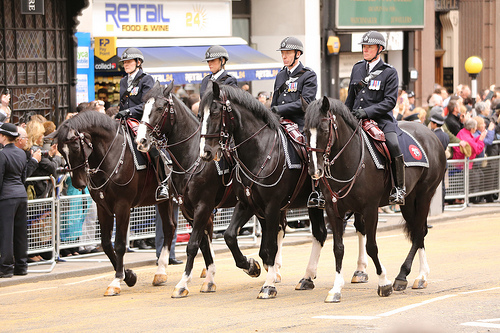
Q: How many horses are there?
A: 4.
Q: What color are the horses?
A: Black.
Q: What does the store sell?
A: Food and wine.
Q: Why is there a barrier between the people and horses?
A: Keep people back.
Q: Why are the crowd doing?
A: Looking down the street.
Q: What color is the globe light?
A: Yellow.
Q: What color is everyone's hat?
A: Black.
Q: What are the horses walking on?
A: Street.